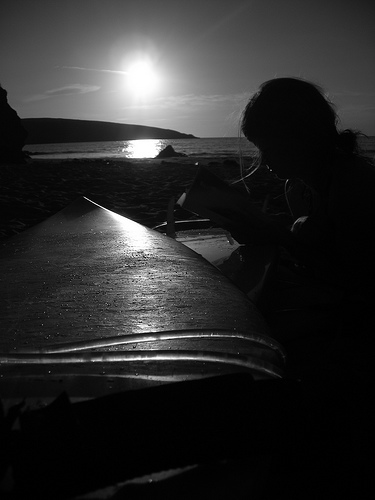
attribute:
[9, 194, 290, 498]
surfboard — curved, wet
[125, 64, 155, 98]
sun — shiny, reflected, reflecting, shining, setting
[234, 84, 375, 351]
woman — reading, sitting, enjoying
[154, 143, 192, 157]
sand — piled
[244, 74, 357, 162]
hair — hanging down, blowing, long